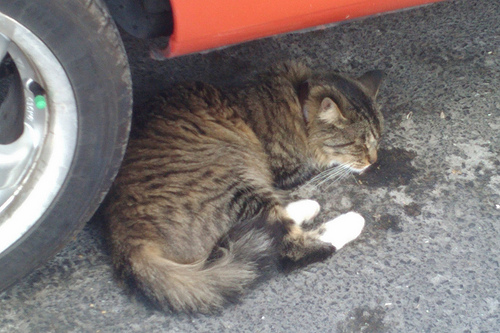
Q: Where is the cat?
A: Under a car.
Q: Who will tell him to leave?
A: The driver.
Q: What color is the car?
A: Red.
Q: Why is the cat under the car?
A: Because the cat likes the shade.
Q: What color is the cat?
A: Brown, black and white.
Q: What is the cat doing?
A: Sleeping.